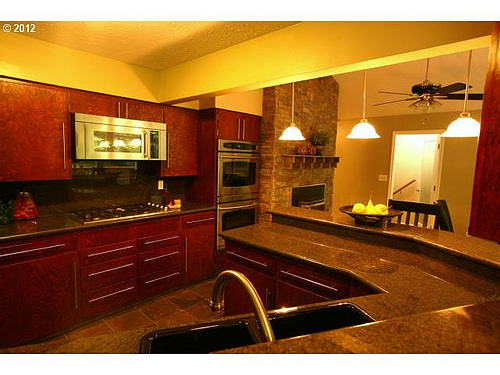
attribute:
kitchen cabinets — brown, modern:
[1, 219, 220, 349]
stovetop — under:
[74, 200, 173, 220]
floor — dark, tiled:
[93, 282, 224, 324]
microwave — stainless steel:
[85, 123, 167, 159]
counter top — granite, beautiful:
[282, 230, 377, 282]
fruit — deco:
[352, 188, 393, 217]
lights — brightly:
[440, 109, 486, 148]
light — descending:
[277, 121, 305, 141]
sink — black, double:
[136, 298, 380, 353]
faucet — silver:
[198, 267, 289, 352]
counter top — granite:
[341, 227, 403, 268]